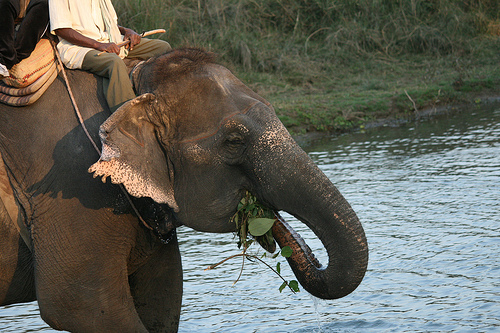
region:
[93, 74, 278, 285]
elephant has big ears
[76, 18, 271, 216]
elephant has big ears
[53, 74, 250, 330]
this is an elephant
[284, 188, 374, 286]
the trunk is coiled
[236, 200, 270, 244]
the mouth has grass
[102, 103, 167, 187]
this is the ear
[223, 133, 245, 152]
the eye is closed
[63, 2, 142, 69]
a man is on the back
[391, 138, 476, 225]
the water is calm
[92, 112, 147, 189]
the ear is cut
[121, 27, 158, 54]
he is holding a stick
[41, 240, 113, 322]
this is the leg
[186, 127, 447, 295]
An elephant is eating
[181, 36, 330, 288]
An elephant is eating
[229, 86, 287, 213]
An elephant is eating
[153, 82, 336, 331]
The elephant is eating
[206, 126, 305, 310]
The elephant is eating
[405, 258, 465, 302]
the water is clear green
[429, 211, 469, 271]
the water is clear green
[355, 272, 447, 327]
the water is clear green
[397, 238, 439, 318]
the water is clear green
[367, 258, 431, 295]
the water is clear green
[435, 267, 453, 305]
the water is clear green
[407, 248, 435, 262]
the water is clear green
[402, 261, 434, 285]
the water is clear green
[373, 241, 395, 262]
the water is clear green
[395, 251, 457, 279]
the water is clear green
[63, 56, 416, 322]
elephant has big ears